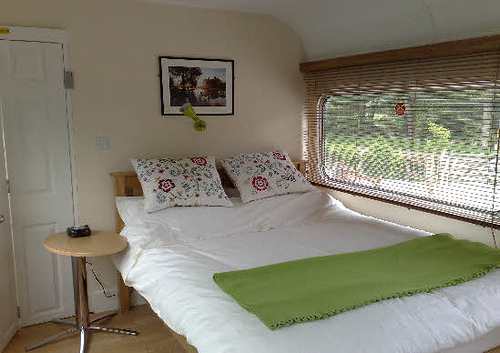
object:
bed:
[106, 149, 498, 352]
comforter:
[118, 193, 500, 351]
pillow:
[127, 152, 232, 212]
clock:
[65, 215, 93, 239]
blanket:
[211, 232, 499, 332]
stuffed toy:
[177, 101, 209, 130]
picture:
[155, 52, 238, 117]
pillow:
[217, 144, 321, 201]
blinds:
[300, 35, 498, 225]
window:
[302, 36, 500, 226]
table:
[40, 231, 129, 352]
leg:
[65, 254, 94, 332]